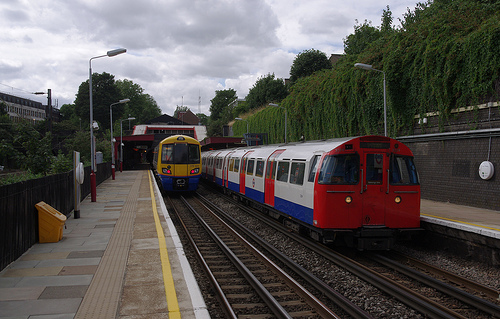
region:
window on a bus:
[386, 153, 416, 182]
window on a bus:
[365, 153, 385, 183]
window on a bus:
[317, 150, 358, 184]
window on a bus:
[287, 160, 304, 184]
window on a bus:
[255, 156, 265, 181]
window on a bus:
[246, 158, 253, 171]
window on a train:
[316, 153, 356, 185]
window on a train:
[363, 151, 383, 184]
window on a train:
[388, 153, 419, 189]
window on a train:
[307, 154, 320, 181]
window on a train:
[287, 157, 304, 182]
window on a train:
[273, 160, 288, 182]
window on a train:
[253, 158, 263, 180]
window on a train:
[244, 159, 254, 173]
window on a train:
[160, 143, 172, 161]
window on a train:
[188, 142, 200, 165]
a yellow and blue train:
[156, 131, 202, 188]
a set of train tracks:
[205, 258, 287, 293]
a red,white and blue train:
[213, 140, 428, 242]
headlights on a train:
[339, 194, 408, 208]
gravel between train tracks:
[312, 266, 404, 304]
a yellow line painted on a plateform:
[140, 165, 176, 317]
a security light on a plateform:
[354, 59, 390, 131]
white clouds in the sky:
[177, 22, 285, 73]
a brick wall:
[421, 152, 447, 201]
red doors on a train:
[257, 147, 284, 209]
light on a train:
[390, 190, 402, 205]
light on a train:
[341, 185, 353, 210]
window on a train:
[291, 152, 307, 187]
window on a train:
[156, 137, 196, 167]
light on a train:
[182, 162, 200, 177]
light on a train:
[156, 161, 167, 176]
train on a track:
[303, 127, 435, 242]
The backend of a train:
[282, 126, 439, 267]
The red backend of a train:
[303, 117, 434, 252]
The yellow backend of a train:
[148, 121, 213, 201]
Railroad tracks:
[162, 186, 281, 309]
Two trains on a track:
[145, 124, 432, 256]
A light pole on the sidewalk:
[80, 42, 135, 214]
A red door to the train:
[255, 141, 291, 217]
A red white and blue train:
[210, 132, 443, 253]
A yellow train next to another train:
[142, 117, 242, 201]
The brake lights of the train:
[156, 159, 208, 182]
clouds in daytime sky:
[0, 0, 426, 116]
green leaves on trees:
[79, 73, 156, 126]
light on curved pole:
[90, 46, 127, 199]